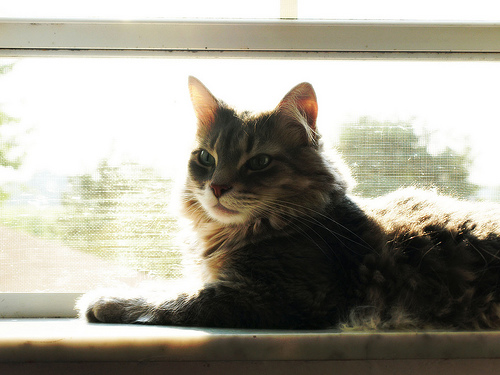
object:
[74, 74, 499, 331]
cat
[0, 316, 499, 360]
window sill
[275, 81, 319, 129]
ear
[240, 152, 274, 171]
eye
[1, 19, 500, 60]
window frame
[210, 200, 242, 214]
mouth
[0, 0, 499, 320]
window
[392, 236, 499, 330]
fur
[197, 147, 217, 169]
eye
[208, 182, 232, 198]
nose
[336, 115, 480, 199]
tree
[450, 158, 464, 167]
leaf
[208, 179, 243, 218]
muzzle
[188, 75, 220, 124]
ear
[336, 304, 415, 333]
belly fur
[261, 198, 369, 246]
whisker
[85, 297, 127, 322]
paw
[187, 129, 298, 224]
face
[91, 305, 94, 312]
claw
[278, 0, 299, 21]
window lock